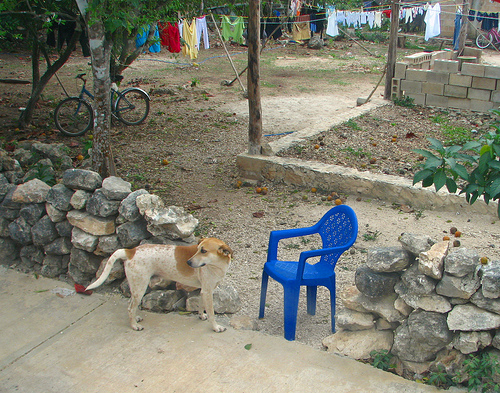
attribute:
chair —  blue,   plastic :
[246, 193, 367, 362]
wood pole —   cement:
[241, 0, 266, 156]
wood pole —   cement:
[380, 1, 400, 101]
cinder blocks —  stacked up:
[391, 45, 497, 112]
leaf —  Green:
[411, 144, 436, 160]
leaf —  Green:
[409, 168, 431, 185]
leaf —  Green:
[431, 168, 447, 191]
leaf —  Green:
[458, 138, 480, 150]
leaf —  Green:
[441, 152, 456, 170]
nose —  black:
[182, 257, 192, 268]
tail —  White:
[77, 244, 132, 294]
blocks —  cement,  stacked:
[386, 43, 498, 116]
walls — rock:
[0, 137, 498, 391]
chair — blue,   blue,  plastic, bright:
[253, 201, 358, 346]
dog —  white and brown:
[83, 237, 233, 332]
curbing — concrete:
[207, 123, 362, 218]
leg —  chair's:
[279, 283, 303, 347]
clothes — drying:
[329, 14, 337, 36]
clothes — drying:
[423, 4, 438, 38]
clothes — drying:
[182, 21, 199, 56]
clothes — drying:
[195, 17, 210, 48]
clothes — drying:
[220, 17, 242, 42]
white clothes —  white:
[325, 10, 384, 37]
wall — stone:
[320, 231, 499, 386]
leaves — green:
[425, 109, 497, 168]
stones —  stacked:
[315, 225, 498, 387]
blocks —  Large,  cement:
[396, 58, 497, 108]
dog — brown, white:
[107, 237, 215, 330]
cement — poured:
[173, 308, 344, 383]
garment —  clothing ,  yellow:
[168, 21, 212, 75]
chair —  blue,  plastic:
[245, 192, 394, 334]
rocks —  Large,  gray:
[53, 151, 243, 277]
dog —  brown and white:
[81, 229, 231, 335]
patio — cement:
[1, 264, 447, 391]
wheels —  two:
[52, 88, 152, 137]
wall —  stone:
[394, 64, 497, 124]